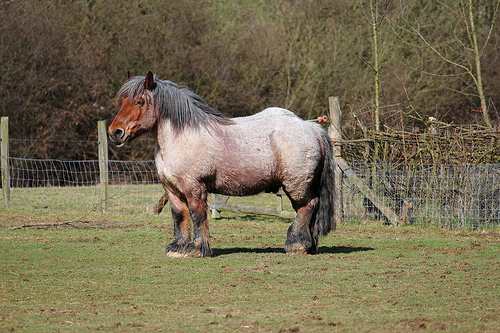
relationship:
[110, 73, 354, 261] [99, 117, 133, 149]
horse has snout